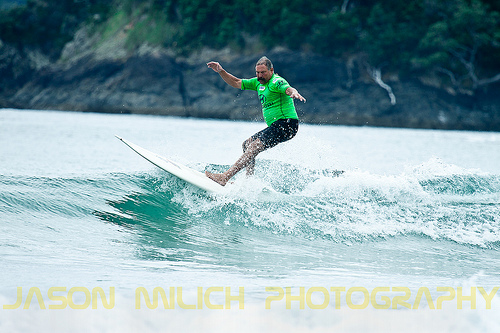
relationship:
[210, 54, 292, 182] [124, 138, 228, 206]
man on top of surfboard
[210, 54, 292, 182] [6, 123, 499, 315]
man in ocean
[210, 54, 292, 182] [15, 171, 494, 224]
man catching wave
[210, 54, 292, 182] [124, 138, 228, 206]
man standing on surfboard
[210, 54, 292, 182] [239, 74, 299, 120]
man wearing shirt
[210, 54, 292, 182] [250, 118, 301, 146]
man wearing shorts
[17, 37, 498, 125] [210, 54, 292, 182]
cliff behind man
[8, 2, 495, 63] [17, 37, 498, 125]
trees on top of cliff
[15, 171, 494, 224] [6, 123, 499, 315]
wave in ocean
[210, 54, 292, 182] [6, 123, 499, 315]
man surfing ocean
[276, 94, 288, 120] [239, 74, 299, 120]
stripe on side of shirt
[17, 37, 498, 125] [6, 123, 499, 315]
cliff near ocean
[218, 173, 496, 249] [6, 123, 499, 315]
foam on top of ocean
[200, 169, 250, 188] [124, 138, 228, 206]
feet on top of surfboard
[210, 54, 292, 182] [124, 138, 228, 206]
man on top a surfboard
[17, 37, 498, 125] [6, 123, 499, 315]
cliff from ocean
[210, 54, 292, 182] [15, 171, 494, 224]
man riding wave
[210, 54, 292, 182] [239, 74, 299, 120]
man in shirt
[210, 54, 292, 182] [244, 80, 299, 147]
man wearing wet suit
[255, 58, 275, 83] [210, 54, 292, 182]
head of man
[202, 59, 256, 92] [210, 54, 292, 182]
arm of man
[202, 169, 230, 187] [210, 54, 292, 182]
feet of man